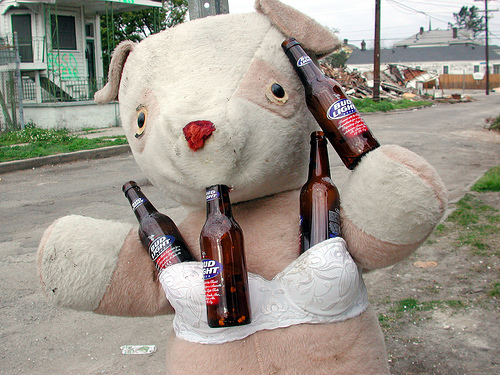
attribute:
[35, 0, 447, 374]
animal — stuffed, white, pink, large, tall, huge, oversized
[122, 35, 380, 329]
bottles — bud light, empty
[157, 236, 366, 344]
bra — white, strapless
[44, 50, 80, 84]
graffiti — green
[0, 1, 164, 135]
house — white, green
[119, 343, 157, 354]
litter — smashed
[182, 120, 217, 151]
nose — red, sad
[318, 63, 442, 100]
junk — large, demolished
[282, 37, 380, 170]
bottle — balanced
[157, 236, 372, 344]
pattern — brocade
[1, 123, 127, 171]
grass — sparse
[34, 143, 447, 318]
paws — soiled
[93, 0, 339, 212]
head — soiled